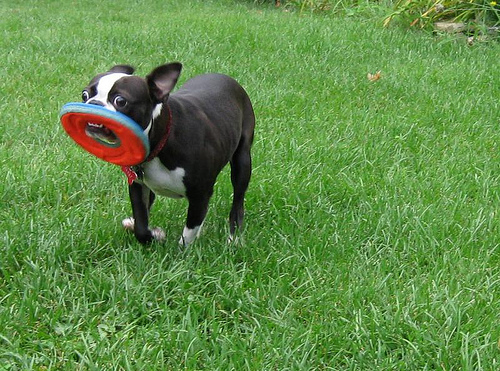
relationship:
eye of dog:
[113, 92, 127, 105] [100, 62, 262, 248]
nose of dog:
[82, 95, 102, 118] [100, 62, 262, 248]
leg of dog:
[167, 172, 207, 251] [100, 62, 262, 248]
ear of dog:
[139, 57, 183, 92] [100, 62, 262, 248]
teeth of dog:
[88, 114, 110, 129] [100, 62, 262, 248]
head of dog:
[78, 63, 177, 119] [100, 62, 262, 248]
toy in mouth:
[56, 105, 145, 172] [88, 119, 100, 135]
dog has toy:
[100, 62, 262, 248] [56, 105, 145, 172]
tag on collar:
[118, 166, 137, 182] [155, 112, 176, 160]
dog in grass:
[100, 62, 262, 248] [270, 36, 322, 73]